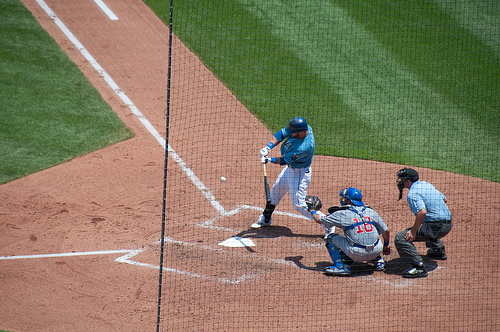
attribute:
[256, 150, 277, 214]
bat — black, tan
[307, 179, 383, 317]
baseball catcher — crouching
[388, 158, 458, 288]
baseball umpire — crouching